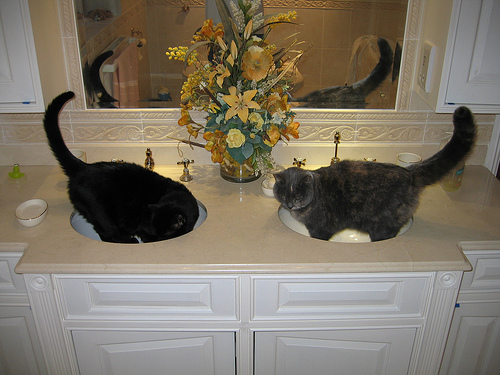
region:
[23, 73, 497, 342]
two cats in a sink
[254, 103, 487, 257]
a gray cat in a sink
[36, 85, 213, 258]
a black cat in a sink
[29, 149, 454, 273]
two sinks on a counter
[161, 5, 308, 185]
a vase with flowers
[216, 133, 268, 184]
vase of glass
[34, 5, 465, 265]
vase in center of counter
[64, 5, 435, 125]
a mirror above sinks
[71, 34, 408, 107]
tails of cats reflecting on a mirror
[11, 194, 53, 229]
a white bowl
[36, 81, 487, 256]
two cats in the sinks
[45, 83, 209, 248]
a black cat in the counter sink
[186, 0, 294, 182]
A pot of flowers on the counter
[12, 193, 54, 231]
a holder for the bar of soap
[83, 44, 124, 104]
the tail of the cat in the mirror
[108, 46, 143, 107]
the pink towel hanging on the wall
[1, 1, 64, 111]
a white wall cabinet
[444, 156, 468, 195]
part of the soap container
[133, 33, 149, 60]
the toilet paper on the roll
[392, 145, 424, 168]
the top of the cup on the counter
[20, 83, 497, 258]
Two cats in two sinks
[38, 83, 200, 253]
A black cat in a sink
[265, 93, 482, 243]
A gray cat in a sink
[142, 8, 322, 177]
Flowers in a bathroom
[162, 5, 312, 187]
Flowers on a bathroom counter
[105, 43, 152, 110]
A towel reflecting in a mirror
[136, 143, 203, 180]
A handle and faucet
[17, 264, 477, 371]
Cupboards under a sink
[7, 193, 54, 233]
A bowl on a bathroom counter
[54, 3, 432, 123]
A mirror in a bathroom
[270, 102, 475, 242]
a grey cat in a sink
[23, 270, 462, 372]
white cabinets under the sink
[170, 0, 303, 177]
a yellow bouquet on the counter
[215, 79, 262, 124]
a lily in the bouquet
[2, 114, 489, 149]
trim over the counter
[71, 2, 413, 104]
a mirror over the sink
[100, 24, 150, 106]
the reflection of a towel in the mirror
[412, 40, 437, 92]
an outlet on the wall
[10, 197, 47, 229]
a dish on the counter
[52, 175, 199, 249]
cat in a sink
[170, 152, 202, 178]
faucet on a counter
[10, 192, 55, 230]
dish on a counter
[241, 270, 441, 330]
drawer in a counter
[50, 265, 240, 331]
drawer on a counter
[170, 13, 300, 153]
flower in a pot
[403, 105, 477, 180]
tail on a cat